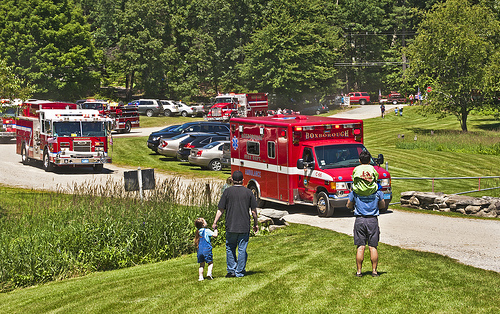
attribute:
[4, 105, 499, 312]
grass — green, cut, lush, gren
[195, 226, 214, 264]
overalls — blue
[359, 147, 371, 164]
hair — dark, long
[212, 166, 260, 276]
man — walking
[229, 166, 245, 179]
hat — black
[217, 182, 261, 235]
pullover — black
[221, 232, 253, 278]
jeans — blue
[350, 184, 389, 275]
man — carrying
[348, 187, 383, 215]
pullover — blue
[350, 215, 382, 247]
shorts — gray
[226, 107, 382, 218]
vehicle — bright, emergency, red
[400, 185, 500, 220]
wall — rock, large, small, brown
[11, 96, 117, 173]
fire truck — red, white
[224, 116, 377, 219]
ambulance — red, white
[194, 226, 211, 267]
outfit — blue, light blue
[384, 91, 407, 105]
truck — black, red, emergency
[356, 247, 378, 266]
calves — bulging, swollen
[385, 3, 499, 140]
tree — green, lush, large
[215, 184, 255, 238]
shirt — large, wide, black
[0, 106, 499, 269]
road — gravel, white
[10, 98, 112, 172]
truck — fire rescue, driving, red, fire fighter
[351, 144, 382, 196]
girl — little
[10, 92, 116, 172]
vehicle — red, emergency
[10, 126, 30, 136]
stripe — white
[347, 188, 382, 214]
tee shirt — blue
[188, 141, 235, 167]
car — parking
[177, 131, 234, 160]
car — parking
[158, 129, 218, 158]
car — parking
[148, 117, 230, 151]
car — parking